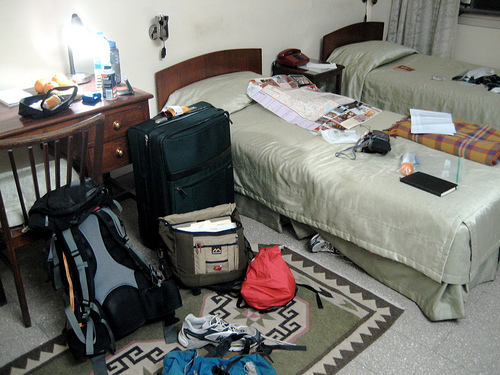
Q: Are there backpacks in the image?
A: Yes, there is a backpack.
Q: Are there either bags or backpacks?
A: Yes, there is a backpack.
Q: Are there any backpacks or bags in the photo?
A: Yes, there is a backpack.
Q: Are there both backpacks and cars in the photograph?
A: No, there is a backpack but no cars.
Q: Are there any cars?
A: No, there are no cars.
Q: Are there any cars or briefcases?
A: No, there are no cars or briefcases.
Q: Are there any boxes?
A: No, there are no boxes.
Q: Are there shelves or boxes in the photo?
A: No, there are no boxes or shelves.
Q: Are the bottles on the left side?
A: Yes, the bottles are on the left of the image.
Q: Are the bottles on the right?
A: No, the bottles are on the left of the image.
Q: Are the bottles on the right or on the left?
A: The bottles are on the left of the image.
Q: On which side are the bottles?
A: The bottles are on the left of the image.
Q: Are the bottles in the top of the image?
A: Yes, the bottles are in the top of the image.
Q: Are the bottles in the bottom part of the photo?
A: No, the bottles are in the top of the image.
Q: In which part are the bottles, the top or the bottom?
A: The bottles are in the top of the image.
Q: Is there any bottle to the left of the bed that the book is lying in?
A: Yes, there are bottles to the left of the bed.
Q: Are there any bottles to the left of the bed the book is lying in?
A: Yes, there are bottles to the left of the bed.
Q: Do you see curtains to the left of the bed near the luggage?
A: No, there are bottles to the left of the bed.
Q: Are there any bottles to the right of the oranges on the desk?
A: Yes, there are bottles to the right of the oranges.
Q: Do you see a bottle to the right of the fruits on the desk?
A: Yes, there are bottles to the right of the oranges.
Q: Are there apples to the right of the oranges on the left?
A: No, there are bottles to the right of the oranges.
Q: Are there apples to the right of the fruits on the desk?
A: No, there are bottles to the right of the oranges.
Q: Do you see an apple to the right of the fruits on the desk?
A: No, there are bottles to the right of the oranges.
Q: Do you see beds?
A: Yes, there is a bed.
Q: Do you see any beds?
A: Yes, there is a bed.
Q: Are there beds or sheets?
A: Yes, there is a bed.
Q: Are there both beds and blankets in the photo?
A: Yes, there are both a bed and a blanket.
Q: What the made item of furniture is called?
A: The piece of furniture is a bed.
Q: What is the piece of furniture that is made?
A: The piece of furniture is a bed.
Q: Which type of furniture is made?
A: The furniture is a bed.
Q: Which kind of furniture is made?
A: The furniture is a bed.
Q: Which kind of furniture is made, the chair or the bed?
A: The bed is made.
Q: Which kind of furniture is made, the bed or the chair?
A: The bed is made.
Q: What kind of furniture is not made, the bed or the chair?
A: The chair is not made.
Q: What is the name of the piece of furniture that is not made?
A: The piece of furniture is a chair.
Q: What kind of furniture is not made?
A: The furniture is a chair.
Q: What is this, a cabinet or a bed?
A: This is a bed.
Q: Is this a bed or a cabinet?
A: This is a bed.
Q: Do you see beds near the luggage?
A: Yes, there is a bed near the luggage.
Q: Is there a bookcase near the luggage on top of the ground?
A: No, there is a bed near the luggage.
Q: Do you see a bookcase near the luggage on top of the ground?
A: No, there is a bed near the luggage.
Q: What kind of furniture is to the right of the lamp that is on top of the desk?
A: The piece of furniture is a bed.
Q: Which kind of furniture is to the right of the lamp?
A: The piece of furniture is a bed.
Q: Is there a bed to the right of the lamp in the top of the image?
A: Yes, there is a bed to the right of the lamp.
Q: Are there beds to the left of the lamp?
A: No, the bed is to the right of the lamp.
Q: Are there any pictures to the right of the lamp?
A: No, there is a bed to the right of the lamp.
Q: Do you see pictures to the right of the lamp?
A: No, there is a bed to the right of the lamp.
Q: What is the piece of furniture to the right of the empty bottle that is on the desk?
A: The piece of furniture is a bed.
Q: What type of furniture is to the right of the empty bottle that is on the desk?
A: The piece of furniture is a bed.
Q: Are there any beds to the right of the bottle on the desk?
A: Yes, there is a bed to the right of the bottle.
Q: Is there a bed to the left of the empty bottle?
A: No, the bed is to the right of the bottle.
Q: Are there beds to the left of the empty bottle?
A: No, the bed is to the right of the bottle.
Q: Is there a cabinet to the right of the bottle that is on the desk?
A: No, there is a bed to the right of the bottle.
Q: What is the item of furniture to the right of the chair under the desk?
A: The piece of furniture is a bed.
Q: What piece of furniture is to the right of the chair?
A: The piece of furniture is a bed.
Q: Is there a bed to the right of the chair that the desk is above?
A: Yes, there is a bed to the right of the chair.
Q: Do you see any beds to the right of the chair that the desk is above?
A: Yes, there is a bed to the right of the chair.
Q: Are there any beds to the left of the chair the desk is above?
A: No, the bed is to the right of the chair.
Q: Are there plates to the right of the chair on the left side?
A: No, there is a bed to the right of the chair.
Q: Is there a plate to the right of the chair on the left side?
A: No, there is a bed to the right of the chair.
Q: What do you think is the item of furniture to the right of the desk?
A: The piece of furniture is a bed.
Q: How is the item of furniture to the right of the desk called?
A: The piece of furniture is a bed.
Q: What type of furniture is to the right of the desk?
A: The piece of furniture is a bed.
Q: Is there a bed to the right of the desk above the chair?
A: Yes, there is a bed to the right of the desk.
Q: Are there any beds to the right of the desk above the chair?
A: Yes, there is a bed to the right of the desk.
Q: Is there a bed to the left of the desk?
A: No, the bed is to the right of the desk.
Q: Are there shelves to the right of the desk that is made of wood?
A: No, there is a bed to the right of the desk.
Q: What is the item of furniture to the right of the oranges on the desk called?
A: The piece of furniture is a bed.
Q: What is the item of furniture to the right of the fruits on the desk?
A: The piece of furniture is a bed.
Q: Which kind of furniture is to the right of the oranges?
A: The piece of furniture is a bed.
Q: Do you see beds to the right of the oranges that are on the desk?
A: Yes, there is a bed to the right of the oranges.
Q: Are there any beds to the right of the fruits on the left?
A: Yes, there is a bed to the right of the oranges.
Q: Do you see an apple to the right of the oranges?
A: No, there is a bed to the right of the oranges.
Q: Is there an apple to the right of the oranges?
A: No, there is a bed to the right of the oranges.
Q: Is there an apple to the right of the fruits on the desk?
A: No, there is a bed to the right of the oranges.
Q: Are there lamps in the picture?
A: Yes, there is a lamp.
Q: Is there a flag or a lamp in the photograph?
A: Yes, there is a lamp.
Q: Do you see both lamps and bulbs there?
A: No, there is a lamp but no light bulbs.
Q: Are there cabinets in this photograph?
A: No, there are no cabinets.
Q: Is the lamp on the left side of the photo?
A: Yes, the lamp is on the left of the image.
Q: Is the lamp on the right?
A: No, the lamp is on the left of the image.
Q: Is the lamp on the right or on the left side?
A: The lamp is on the left of the image.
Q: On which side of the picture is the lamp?
A: The lamp is on the left of the image.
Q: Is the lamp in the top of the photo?
A: Yes, the lamp is in the top of the image.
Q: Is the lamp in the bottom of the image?
A: No, the lamp is in the top of the image.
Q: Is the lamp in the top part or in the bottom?
A: The lamp is in the top of the image.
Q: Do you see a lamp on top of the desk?
A: Yes, there is a lamp on top of the desk.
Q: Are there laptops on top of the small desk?
A: No, there is a lamp on top of the desk.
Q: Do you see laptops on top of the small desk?
A: No, there is a lamp on top of the desk.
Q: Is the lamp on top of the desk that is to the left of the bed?
A: Yes, the lamp is on top of the desk.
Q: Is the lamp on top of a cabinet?
A: No, the lamp is on top of the desk.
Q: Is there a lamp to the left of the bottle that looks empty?
A: Yes, there is a lamp to the left of the bottle.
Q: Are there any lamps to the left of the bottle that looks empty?
A: Yes, there is a lamp to the left of the bottle.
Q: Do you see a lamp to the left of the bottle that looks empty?
A: Yes, there is a lamp to the left of the bottle.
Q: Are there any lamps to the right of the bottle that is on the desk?
A: No, the lamp is to the left of the bottle.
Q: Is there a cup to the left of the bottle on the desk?
A: No, there is a lamp to the left of the bottle.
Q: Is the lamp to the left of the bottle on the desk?
A: Yes, the lamp is to the left of the bottle.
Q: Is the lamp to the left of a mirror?
A: No, the lamp is to the left of the bottle.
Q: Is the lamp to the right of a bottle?
A: No, the lamp is to the left of a bottle.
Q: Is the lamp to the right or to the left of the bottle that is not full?
A: The lamp is to the left of the bottle.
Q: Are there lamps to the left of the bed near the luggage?
A: Yes, there is a lamp to the left of the bed.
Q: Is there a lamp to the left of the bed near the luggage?
A: Yes, there is a lamp to the left of the bed.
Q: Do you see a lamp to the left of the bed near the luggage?
A: Yes, there is a lamp to the left of the bed.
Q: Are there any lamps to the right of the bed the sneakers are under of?
A: No, the lamp is to the left of the bed.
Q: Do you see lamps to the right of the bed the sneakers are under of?
A: No, the lamp is to the left of the bed.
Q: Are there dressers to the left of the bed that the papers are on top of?
A: No, there is a lamp to the left of the bed.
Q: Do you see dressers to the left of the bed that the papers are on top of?
A: No, there is a lamp to the left of the bed.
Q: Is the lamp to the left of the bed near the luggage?
A: Yes, the lamp is to the left of the bed.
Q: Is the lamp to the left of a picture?
A: No, the lamp is to the left of the bed.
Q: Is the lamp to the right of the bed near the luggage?
A: No, the lamp is to the left of the bed.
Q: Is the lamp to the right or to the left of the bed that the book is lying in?
A: The lamp is to the left of the bed.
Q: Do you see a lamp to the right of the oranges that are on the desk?
A: Yes, there is a lamp to the right of the oranges.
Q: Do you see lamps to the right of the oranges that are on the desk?
A: Yes, there is a lamp to the right of the oranges.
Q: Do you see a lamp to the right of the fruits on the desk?
A: Yes, there is a lamp to the right of the oranges.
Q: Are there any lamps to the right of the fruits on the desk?
A: Yes, there is a lamp to the right of the oranges.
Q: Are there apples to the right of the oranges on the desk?
A: No, there is a lamp to the right of the oranges.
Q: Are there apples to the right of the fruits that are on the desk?
A: No, there is a lamp to the right of the oranges.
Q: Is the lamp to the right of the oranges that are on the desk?
A: Yes, the lamp is to the right of the oranges.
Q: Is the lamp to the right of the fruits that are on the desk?
A: Yes, the lamp is to the right of the oranges.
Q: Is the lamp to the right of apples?
A: No, the lamp is to the right of the oranges.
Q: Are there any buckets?
A: No, there are no buckets.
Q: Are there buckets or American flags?
A: No, there are no buckets or American flags.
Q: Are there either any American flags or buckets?
A: No, there are no buckets or American flags.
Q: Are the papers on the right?
A: Yes, the papers are on the right of the image.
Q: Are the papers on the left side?
A: No, the papers are on the right of the image.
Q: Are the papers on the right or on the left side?
A: The papers are on the right of the image.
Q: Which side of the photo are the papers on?
A: The papers are on the right of the image.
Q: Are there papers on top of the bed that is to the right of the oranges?
A: Yes, there are papers on top of the bed.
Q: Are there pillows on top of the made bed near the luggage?
A: No, there are papers on top of the bed.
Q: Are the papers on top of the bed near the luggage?
A: Yes, the papers are on top of the bed.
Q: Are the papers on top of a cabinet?
A: No, the papers are on top of the bed.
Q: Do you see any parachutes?
A: No, there are no parachutes.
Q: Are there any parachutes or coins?
A: No, there are no parachutes or coins.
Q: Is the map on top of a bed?
A: Yes, the map is on top of a bed.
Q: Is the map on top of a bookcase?
A: No, the map is on top of a bed.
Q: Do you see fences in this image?
A: No, there are no fences.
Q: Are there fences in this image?
A: No, there are no fences.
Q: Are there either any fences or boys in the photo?
A: No, there are no fences or boys.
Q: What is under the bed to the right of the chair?
A: The sneakers are under the bed.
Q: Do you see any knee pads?
A: No, there are no knee pads.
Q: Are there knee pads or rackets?
A: No, there are no knee pads or rackets.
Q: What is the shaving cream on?
A: The shaving cream is on the desk.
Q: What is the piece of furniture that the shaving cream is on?
A: The piece of furniture is a desk.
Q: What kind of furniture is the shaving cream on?
A: The shaving cream is on the desk.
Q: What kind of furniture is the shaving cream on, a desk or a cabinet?
A: The shaving cream is on a desk.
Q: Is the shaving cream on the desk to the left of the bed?
A: Yes, the shaving cream is on the desk.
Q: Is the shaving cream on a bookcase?
A: No, the shaving cream is on the desk.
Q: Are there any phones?
A: Yes, there is a phone.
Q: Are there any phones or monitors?
A: Yes, there is a phone.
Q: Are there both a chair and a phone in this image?
A: Yes, there are both a phone and a chair.